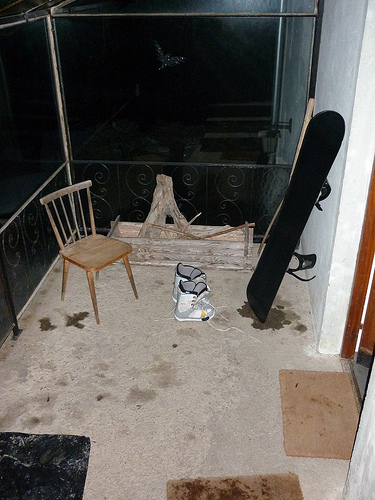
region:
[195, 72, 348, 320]
snowboard leadning against the wall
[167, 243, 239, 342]
snow boots on the floor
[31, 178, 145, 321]
wooden dining room chair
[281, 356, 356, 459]
welcome mat rub in front of door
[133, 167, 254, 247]
pieces of wood in a box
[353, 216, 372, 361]
wooden door that is open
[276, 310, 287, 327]
water spots on the floor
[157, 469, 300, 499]
wet pieces of carpet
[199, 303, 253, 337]
laces of snow boots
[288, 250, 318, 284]
snowboard boot bindings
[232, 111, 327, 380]
the snowboard is black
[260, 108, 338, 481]
the snowboard is black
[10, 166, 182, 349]
the chair is empty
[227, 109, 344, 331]
The snow board is black.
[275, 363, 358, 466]
The rug is tan.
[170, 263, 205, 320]
The boots are white.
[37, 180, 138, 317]
The chair is brown.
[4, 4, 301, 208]
The fence is black.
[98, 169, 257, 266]
The wood is on the porch.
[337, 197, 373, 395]
The door is open.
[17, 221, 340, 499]
The floor is grey.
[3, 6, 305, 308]
It is night outside.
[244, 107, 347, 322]
Black snowboard leaning against wall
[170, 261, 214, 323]
Snowboard boots on the ground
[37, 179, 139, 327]
Wooden chair by the railing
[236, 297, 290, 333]
Wet spot under snowboard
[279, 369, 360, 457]
Tan mat in front of door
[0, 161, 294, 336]
Wrought-iron railing around porch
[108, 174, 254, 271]
Piece of wood in a wooden container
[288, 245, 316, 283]
Black binding on snowboard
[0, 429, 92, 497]
Black rug on porch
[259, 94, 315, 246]
Long stick leaning against wall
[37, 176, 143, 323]
wooden brown distressed wood chair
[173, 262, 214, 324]
white and grey ski boots with black tips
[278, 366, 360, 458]
dirty light brown area rug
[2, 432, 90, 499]
corner of black and grey area rug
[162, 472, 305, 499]
edge of light brown area rug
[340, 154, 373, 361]
dark brown door trim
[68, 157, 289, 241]
wrought iron railing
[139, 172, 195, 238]
light grey and brown drift wood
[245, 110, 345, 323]
black shiny snowboard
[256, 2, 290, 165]
dark grey metal light post